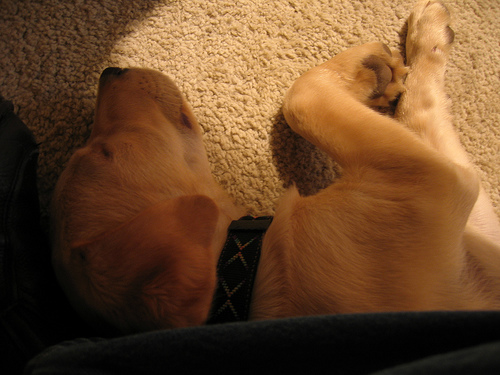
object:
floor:
[3, 5, 497, 196]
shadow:
[31, 6, 104, 60]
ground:
[0, 0, 292, 76]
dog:
[48, 0, 499, 329]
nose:
[98, 66, 126, 85]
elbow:
[419, 157, 483, 211]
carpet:
[144, 0, 304, 63]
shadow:
[279, 155, 323, 195]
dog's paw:
[328, 41, 415, 107]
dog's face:
[104, 129, 189, 207]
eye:
[99, 143, 112, 158]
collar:
[206, 213, 274, 325]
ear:
[68, 193, 222, 329]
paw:
[402, 0, 458, 68]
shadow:
[5, 190, 48, 355]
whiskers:
[133, 76, 193, 111]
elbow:
[281, 73, 358, 131]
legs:
[281, 0, 500, 237]